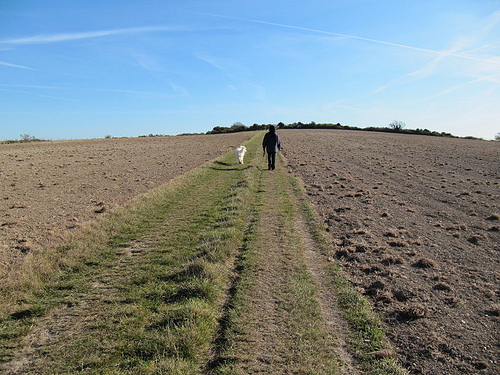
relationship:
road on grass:
[0, 132, 374, 375] [2, 130, 402, 372]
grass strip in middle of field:
[12, 132, 409, 372] [5, 131, 497, 373]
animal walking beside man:
[235, 146, 246, 165] [261, 114, 290, 181]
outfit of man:
[262, 132, 278, 162] [261, 125, 283, 172]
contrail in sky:
[249, 20, 490, 82] [1, 6, 153, 136]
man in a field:
[262, 125, 282, 170] [5, 131, 497, 373]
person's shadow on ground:
[209, 154, 255, 196] [222, 164, 267, 201]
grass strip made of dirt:
[0, 132, 500, 374] [198, 160, 350, 365]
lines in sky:
[183, 6, 469, 75] [2, 0, 497, 145]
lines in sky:
[374, 46, 473, 91] [2, 0, 497, 145]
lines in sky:
[2, 19, 234, 44] [2, 0, 497, 145]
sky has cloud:
[2, 4, 499, 126] [380, 11, 499, 92]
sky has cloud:
[2, 4, 499, 126] [335, 28, 498, 87]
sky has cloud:
[2, 4, 499, 126] [0, 17, 240, 46]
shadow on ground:
[211, 159, 234, 166] [0, 137, 234, 373]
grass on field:
[181, 194, 269, 256] [15, 139, 497, 359]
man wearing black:
[262, 125, 282, 170] [262, 123, 284, 169]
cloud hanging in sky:
[1, 0, 500, 138] [2, 0, 497, 145]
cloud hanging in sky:
[1, 60, 44, 73] [2, 0, 497, 145]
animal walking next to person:
[235, 146, 246, 165] [260, 124, 284, 172]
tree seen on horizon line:
[228, 120, 247, 131] [28, 105, 481, 131]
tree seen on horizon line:
[387, 120, 405, 130] [28, 105, 481, 131]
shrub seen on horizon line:
[204, 130, 214, 135] [28, 105, 481, 131]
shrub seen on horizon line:
[342, 124, 350, 130] [28, 105, 481, 131]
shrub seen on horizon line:
[352, 124, 362, 129] [28, 105, 481, 131]